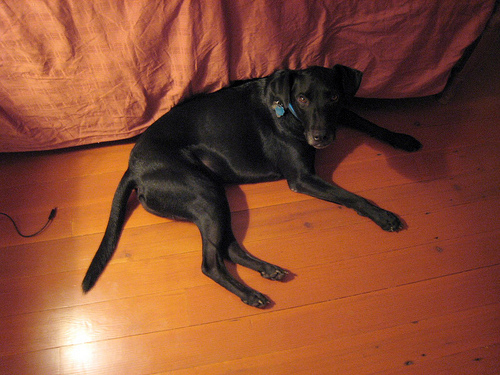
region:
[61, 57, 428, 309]
a dog sitting on the ground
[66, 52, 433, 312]
the dog is black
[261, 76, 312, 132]
the dog is wearing a collar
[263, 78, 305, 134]
the collar is blue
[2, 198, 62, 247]
a cord on the floor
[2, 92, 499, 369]
the floor is wooden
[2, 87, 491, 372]
the floorboards are reddish brown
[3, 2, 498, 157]
the dog is leaning on the bedding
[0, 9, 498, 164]
the bed is behind the dog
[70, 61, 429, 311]
the dog is facing forwards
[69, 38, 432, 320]
black dog on floor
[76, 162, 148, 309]
black dog tail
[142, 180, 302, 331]
black dog back legs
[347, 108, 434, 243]
black dog front legs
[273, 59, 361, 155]
black dog face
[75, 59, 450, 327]
black dog with blue collar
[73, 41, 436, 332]
black dog with four legs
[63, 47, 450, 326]
black dog on wooden floor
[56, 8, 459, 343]
black dog near sheet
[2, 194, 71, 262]
black cord on wooden floor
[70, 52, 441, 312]
a dog lying on the floor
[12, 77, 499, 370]
floor of room is brown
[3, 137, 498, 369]
floor of room is made of parket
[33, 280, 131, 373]
part of the floor shines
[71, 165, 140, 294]
long tail of dog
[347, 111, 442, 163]
left leg of dog is extended to the front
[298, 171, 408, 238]
right leg of dog is extended to the front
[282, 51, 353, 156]
dog wears a blue collar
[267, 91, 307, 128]
blue collar of dog has a blue pendant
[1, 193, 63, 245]
a black wire on the floor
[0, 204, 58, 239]
a small black electrical cord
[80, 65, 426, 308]
a black dog laying on a floor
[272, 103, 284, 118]
a small blue tag hanging from a collar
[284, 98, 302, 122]
a light blue collar around a dogs neck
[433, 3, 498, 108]
a brown wooden bed post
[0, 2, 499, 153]
a brown patterned bed sheet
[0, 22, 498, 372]
an brownish orange wood floor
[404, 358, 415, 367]
a small black knot in the wooden floor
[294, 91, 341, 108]
beautiful dark brown dog eyes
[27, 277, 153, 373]
light reflecting off the wood floor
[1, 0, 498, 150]
a wrinkled red sheet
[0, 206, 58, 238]
a black electrical cord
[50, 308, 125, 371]
light reflecting off the wood floor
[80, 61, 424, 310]
a black dog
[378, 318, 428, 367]
a few knots in the wood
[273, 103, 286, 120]
a few metal dog tags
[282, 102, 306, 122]
a bright blue dog collar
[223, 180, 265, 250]
a shadow on the wood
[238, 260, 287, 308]
a pair of dog feet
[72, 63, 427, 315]
a dog laying on a wood floor